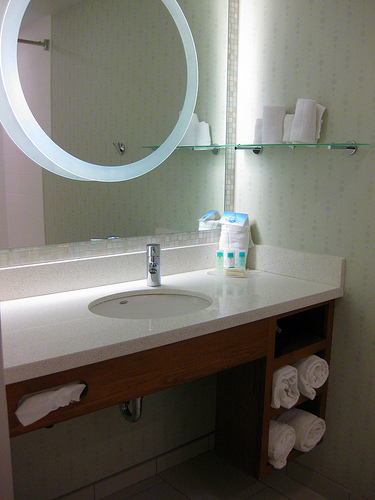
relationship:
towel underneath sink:
[271, 366, 303, 410] [88, 288, 214, 321]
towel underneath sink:
[292, 353, 329, 400] [88, 288, 214, 321]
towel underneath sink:
[269, 421, 296, 473] [88, 288, 214, 321]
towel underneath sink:
[276, 407, 325, 452] [88, 288, 214, 321]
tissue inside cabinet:
[14, 383, 87, 428] [6, 301, 334, 480]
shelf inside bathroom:
[231, 142, 367, 148] [1, 1, 374, 500]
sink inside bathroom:
[88, 288, 214, 321] [1, 1, 374, 500]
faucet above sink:
[146, 243, 164, 289] [88, 288, 214, 321]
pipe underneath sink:
[120, 396, 145, 425] [88, 288, 214, 321]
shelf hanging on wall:
[231, 142, 367, 148] [234, 2, 374, 500]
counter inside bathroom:
[0, 240, 346, 385] [1, 1, 374, 500]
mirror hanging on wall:
[1, 1, 238, 256] [1, 1, 240, 500]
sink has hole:
[88, 288, 214, 321] [120, 300, 132, 306]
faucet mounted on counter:
[146, 243, 164, 289] [0, 240, 346, 385]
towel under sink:
[271, 366, 303, 410] [88, 288, 214, 321]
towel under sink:
[292, 353, 329, 400] [88, 288, 214, 321]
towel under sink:
[269, 421, 296, 473] [88, 288, 214, 321]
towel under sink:
[276, 407, 325, 452] [88, 288, 214, 321]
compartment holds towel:
[267, 350, 329, 466] [271, 366, 303, 410]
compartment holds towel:
[267, 350, 329, 466] [292, 353, 329, 400]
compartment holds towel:
[267, 350, 329, 466] [269, 421, 296, 473]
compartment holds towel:
[267, 350, 329, 466] [276, 407, 325, 452]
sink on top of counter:
[88, 288, 214, 321] [0, 240, 346, 385]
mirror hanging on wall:
[1, 1, 200, 184] [1, 1, 240, 500]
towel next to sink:
[217, 222, 253, 267] [88, 288, 214, 321]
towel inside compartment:
[271, 366, 303, 410] [267, 350, 329, 466]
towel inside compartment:
[292, 353, 329, 400] [267, 350, 329, 466]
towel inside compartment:
[269, 421, 296, 473] [267, 350, 329, 466]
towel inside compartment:
[276, 407, 325, 452] [267, 350, 329, 466]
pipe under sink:
[120, 396, 145, 425] [88, 288, 214, 321]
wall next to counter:
[234, 2, 374, 500] [0, 240, 346, 385]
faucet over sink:
[146, 243, 164, 289] [88, 288, 214, 321]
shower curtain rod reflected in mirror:
[17, 38, 51, 50] [1, 1, 200, 184]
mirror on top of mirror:
[1, 1, 200, 184] [1, 1, 238, 256]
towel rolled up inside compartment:
[271, 366, 303, 410] [267, 350, 329, 466]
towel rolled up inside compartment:
[292, 353, 329, 400] [267, 350, 329, 466]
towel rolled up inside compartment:
[269, 421, 296, 473] [267, 350, 329, 466]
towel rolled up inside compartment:
[276, 407, 325, 452] [267, 350, 329, 466]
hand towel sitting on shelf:
[262, 105, 288, 145] [231, 142, 367, 148]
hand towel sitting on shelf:
[287, 98, 325, 149] [231, 142, 367, 148]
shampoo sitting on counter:
[215, 251, 224, 269] [0, 240, 346, 385]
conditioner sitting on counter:
[225, 249, 236, 269] [0, 240, 346, 385]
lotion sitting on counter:
[235, 246, 248, 267] [0, 240, 346, 385]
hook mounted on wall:
[113, 142, 127, 154] [44, 1, 229, 246]